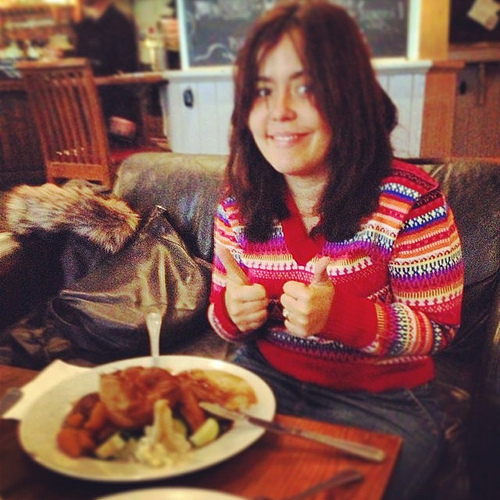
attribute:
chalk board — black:
[182, 0, 410, 68]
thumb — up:
[211, 243, 247, 279]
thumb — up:
[312, 256, 332, 282]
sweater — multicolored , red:
[209, 161, 463, 371]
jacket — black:
[2, 182, 136, 355]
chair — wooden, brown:
[14, 56, 125, 186]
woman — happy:
[209, 1, 464, 379]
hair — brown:
[229, 1, 376, 96]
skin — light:
[301, 110, 320, 127]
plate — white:
[19, 352, 275, 480]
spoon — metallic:
[144, 309, 164, 368]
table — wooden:
[3, 361, 403, 498]